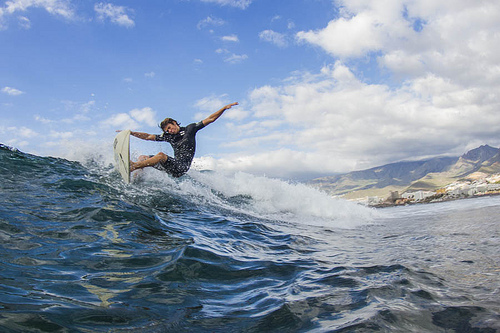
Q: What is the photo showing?
A: It is showing an ocean.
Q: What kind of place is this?
A: It is an ocean.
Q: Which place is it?
A: It is an ocean.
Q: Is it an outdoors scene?
A: Yes, it is outdoors.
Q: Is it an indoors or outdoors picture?
A: It is outdoors.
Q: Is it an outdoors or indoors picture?
A: It is outdoors.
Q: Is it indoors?
A: No, it is outdoors.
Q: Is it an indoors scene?
A: No, it is outdoors.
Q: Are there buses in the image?
A: No, there are no buses.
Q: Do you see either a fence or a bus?
A: No, there are no buses or fences.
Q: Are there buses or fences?
A: No, there are no buses or fences.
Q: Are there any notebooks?
A: No, there are no notebooks.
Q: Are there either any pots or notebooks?
A: No, there are no notebooks or pots.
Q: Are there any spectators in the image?
A: No, there are no spectators.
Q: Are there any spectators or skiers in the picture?
A: No, there are no spectators or skiers.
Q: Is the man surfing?
A: Yes, the man is surfing.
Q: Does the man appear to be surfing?
A: Yes, the man is surfing.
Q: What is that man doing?
A: The man is surfing.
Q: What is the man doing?
A: The man is surfing.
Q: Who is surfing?
A: The man is surfing.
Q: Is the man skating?
A: No, the man is surfing.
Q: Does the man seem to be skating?
A: No, the man is surfing.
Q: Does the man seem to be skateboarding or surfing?
A: The man is surfing.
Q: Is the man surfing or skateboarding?
A: The man is surfing.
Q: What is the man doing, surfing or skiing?
A: The man is surfing.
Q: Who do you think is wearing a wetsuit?
A: The man is wearing a wetsuit.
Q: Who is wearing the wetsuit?
A: The man is wearing a wetsuit.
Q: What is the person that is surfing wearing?
A: The man is wearing a wetsuit.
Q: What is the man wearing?
A: The man is wearing a wetsuit.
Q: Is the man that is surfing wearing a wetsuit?
A: Yes, the man is wearing a wetsuit.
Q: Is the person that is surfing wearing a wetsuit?
A: Yes, the man is wearing a wetsuit.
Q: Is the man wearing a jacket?
A: No, the man is wearing a wetsuit.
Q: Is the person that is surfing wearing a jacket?
A: No, the man is wearing a wetsuit.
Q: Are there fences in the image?
A: No, there are no fences.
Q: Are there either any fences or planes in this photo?
A: No, there are no fences or planes.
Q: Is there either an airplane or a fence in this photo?
A: No, there are no fences or airplanes.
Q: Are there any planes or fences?
A: No, there are no fences or planes.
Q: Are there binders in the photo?
A: No, there are no binders.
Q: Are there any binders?
A: No, there are no binders.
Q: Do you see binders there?
A: No, there are no binders.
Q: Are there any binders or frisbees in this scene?
A: No, there are no binders or frisbees.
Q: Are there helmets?
A: No, there are no helmets.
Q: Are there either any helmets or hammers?
A: No, there are no helmets or hammers.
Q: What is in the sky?
A: The clouds are in the sky.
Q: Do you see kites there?
A: No, there are no kites.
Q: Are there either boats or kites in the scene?
A: No, there are no kites or boats.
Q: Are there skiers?
A: No, there are no skiers.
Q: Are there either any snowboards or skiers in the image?
A: No, there are no skiers or snowboards.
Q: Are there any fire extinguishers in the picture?
A: No, there are no fire extinguishers.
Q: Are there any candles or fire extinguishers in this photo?
A: No, there are no fire extinguishers or candles.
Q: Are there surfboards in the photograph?
A: Yes, there is a surfboard.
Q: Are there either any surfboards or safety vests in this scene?
A: Yes, there is a surfboard.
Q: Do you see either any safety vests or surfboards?
A: Yes, there is a surfboard.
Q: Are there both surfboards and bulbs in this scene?
A: No, there is a surfboard but no light bulbs.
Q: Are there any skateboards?
A: No, there are no skateboards.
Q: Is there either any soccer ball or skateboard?
A: No, there are no skateboards or soccer balls.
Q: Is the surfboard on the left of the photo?
A: Yes, the surfboard is on the left of the image.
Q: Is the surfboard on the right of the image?
A: No, the surfboard is on the left of the image.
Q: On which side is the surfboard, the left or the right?
A: The surfboard is on the left of the image.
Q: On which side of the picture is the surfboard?
A: The surfboard is on the left of the image.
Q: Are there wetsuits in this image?
A: Yes, there is a wetsuit.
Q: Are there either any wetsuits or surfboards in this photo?
A: Yes, there is a wetsuit.